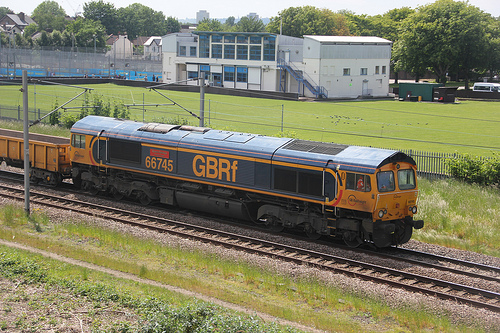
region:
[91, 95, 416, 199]
the train is yellow and black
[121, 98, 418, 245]
the trian engine in front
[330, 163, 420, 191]
the train has windows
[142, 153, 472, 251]
the train is metal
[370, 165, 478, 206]
the windows are glass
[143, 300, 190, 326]
the grass is short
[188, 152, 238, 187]
letters that are orange on the train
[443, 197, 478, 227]
the grass is tall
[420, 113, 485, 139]
the lawn is green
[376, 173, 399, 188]
a windshield on the train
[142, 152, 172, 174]
numbers on the train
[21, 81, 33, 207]
a grey pole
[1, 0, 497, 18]
light in daytime sky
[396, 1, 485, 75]
green leaves on tree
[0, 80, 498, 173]
neatly trimmed green grass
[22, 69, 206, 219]
metal poles over train tracks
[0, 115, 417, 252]
side of freight train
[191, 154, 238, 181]
yellow letters of train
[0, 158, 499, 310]
two sets of train tracks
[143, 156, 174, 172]
number on side of train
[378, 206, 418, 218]
two lights on front of train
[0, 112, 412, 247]
train traveling down the tracks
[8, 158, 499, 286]
track train is on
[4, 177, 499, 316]
unused tracks next to train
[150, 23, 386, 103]
white building beyond the train tracks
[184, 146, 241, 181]
yellow lettering on train car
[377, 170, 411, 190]
front windows on train car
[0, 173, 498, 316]
gravel around the train tracks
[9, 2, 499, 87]
trees behind the building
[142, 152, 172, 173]
yellow numbers on train car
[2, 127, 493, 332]
grass around the train tracks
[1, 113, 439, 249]
Yellow and gray train on tracks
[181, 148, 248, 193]
Yellow capital letters on the train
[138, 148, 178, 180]
Yellow numbers on the train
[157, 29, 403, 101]
White and blue building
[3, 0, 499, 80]
Trees behind the building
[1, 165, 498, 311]
Train tracks on the ground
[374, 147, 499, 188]
Fence behind the train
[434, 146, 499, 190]
Bushes next to the fence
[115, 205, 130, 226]
wooden plank on track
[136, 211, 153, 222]
wooden plank on track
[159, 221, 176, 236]
wooden plank on track